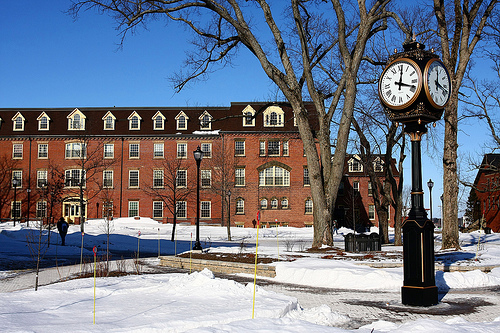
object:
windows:
[149, 165, 166, 191]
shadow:
[83, 298, 179, 322]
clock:
[421, 57, 453, 107]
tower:
[380, 42, 450, 307]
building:
[0, 96, 333, 231]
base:
[400, 284, 439, 306]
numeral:
[398, 96, 405, 104]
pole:
[184, 144, 214, 251]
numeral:
[382, 83, 392, 90]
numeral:
[409, 70, 416, 77]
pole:
[398, 119, 442, 307]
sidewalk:
[135, 254, 499, 331]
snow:
[0, 215, 496, 326]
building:
[463, 150, 499, 232]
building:
[330, 150, 402, 227]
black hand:
[397, 64, 403, 90]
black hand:
[393, 80, 413, 88]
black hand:
[434, 66, 440, 91]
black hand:
[433, 79, 447, 92]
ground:
[348, 148, 378, 178]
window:
[125, 139, 143, 163]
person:
[53, 217, 71, 247]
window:
[10, 109, 29, 137]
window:
[31, 100, 58, 147]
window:
[65, 104, 93, 144]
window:
[90, 102, 122, 137]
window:
[125, 102, 142, 136]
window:
[151, 104, 168, 138]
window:
[188, 104, 215, 137]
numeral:
[439, 67, 444, 74]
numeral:
[440, 95, 445, 103]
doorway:
[63, 197, 85, 223]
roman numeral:
[383, 74, 394, 82]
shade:
[2, 226, 260, 281]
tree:
[66, 0, 402, 254]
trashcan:
[342, 233, 353, 250]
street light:
[191, 146, 205, 252]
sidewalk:
[24, 232, 165, 257]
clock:
[372, 59, 425, 114]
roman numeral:
[410, 78, 420, 84]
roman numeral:
[389, 93, 399, 104]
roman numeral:
[390, 68, 399, 76]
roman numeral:
[396, 63, 405, 72]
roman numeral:
[403, 64, 411, 74]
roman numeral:
[403, 91, 413, 100]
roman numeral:
[407, 84, 418, 94]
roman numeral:
[384, 88, 394, 99]